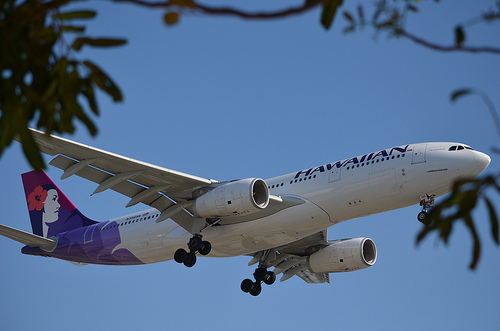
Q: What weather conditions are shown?
A: It is clear.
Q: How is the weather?
A: It is clear.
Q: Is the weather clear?
A: Yes, it is clear.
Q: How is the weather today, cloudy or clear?
A: It is clear.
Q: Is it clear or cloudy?
A: It is clear.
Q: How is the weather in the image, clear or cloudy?
A: It is clear.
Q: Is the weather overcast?
A: No, it is clear.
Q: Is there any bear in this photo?
A: No, there are no bears.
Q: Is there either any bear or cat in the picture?
A: No, there are no bears or cats.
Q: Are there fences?
A: No, there are no fences.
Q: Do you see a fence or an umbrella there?
A: No, there are no fences or umbrellas.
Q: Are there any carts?
A: No, there are no carts.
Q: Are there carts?
A: No, there are no carts.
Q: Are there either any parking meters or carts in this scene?
A: No, there are no carts or parking meters.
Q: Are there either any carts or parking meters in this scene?
A: No, there are no carts or parking meters.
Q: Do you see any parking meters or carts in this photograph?
A: No, there are no carts or parking meters.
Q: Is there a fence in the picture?
A: No, there are no fences.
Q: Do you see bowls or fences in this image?
A: No, there are no fences or bowls.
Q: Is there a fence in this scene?
A: No, there are no fences.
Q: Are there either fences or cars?
A: No, there are no fences or cars.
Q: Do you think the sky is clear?
A: Yes, the sky is clear.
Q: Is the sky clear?
A: Yes, the sky is clear.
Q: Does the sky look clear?
A: Yes, the sky is clear.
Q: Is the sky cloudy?
A: No, the sky is clear.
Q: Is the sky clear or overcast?
A: The sky is clear.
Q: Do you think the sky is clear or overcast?
A: The sky is clear.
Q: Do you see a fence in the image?
A: No, there are no fences.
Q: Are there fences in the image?
A: No, there are no fences.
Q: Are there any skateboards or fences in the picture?
A: No, there are no fences or skateboards.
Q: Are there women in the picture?
A: Yes, there is a woman.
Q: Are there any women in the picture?
A: Yes, there is a woman.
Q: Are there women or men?
A: Yes, there is a woman.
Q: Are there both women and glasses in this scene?
A: No, there is a woman but no glasses.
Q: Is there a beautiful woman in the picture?
A: Yes, there is a beautiful woman.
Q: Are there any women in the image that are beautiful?
A: Yes, there is a woman that is beautiful.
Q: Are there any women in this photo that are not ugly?
A: Yes, there is an beautiful woman.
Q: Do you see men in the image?
A: No, there are no men.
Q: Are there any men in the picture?
A: No, there are no men.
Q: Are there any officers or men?
A: No, there are no men or officers.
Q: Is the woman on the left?
A: Yes, the woman is on the left of the image.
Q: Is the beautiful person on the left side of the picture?
A: Yes, the woman is on the left of the image.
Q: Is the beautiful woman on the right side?
A: No, the woman is on the left of the image.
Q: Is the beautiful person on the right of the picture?
A: No, the woman is on the left of the image.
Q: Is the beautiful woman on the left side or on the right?
A: The woman is on the left of the image.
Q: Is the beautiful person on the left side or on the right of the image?
A: The woman is on the left of the image.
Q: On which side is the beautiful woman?
A: The woman is on the left of the image.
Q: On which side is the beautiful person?
A: The woman is on the left of the image.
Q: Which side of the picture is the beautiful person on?
A: The woman is on the left of the image.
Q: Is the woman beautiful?
A: Yes, the woman is beautiful.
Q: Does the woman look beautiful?
A: Yes, the woman is beautiful.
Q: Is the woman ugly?
A: No, the woman is beautiful.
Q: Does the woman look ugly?
A: No, the woman is beautiful.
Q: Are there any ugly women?
A: No, there is a woman but she is beautiful.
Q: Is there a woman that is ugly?
A: No, there is a woman but she is beautiful.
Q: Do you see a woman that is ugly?
A: No, there is a woman but she is beautiful.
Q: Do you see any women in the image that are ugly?
A: No, there is a woman but she is beautiful.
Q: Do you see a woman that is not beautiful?
A: No, there is a woman but she is beautiful.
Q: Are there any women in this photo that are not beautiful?
A: No, there is a woman but she is beautiful.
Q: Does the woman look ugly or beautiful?
A: The woman is beautiful.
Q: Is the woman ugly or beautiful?
A: The woman is beautiful.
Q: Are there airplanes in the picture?
A: Yes, there is an airplane.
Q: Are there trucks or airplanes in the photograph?
A: Yes, there is an airplane.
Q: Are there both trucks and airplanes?
A: No, there is an airplane but no trucks.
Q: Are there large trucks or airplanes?
A: Yes, there is a large airplane.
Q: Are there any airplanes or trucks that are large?
A: Yes, the airplane is large.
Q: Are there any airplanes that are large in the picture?
A: Yes, there is a large airplane.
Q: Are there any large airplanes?
A: Yes, there is a large airplane.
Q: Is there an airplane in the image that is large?
A: Yes, there is an airplane that is large.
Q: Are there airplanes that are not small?
A: Yes, there is a large airplane.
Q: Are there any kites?
A: No, there are no kites.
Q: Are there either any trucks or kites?
A: No, there are no kites or trucks.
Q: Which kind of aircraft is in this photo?
A: The aircraft is an airplane.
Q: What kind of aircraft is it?
A: The aircraft is an airplane.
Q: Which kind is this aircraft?
A: This is an airplane.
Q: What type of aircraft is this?
A: This is an airplane.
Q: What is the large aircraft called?
A: The aircraft is an airplane.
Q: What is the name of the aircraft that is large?
A: The aircraft is an airplane.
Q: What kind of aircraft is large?
A: The aircraft is an airplane.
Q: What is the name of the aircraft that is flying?
A: The aircraft is an airplane.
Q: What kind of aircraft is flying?
A: The aircraft is an airplane.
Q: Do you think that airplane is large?
A: Yes, the airplane is large.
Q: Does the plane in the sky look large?
A: Yes, the airplane is large.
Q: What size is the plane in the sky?
A: The plane is large.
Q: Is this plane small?
A: No, the plane is large.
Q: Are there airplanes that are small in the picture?
A: No, there is an airplane but it is large.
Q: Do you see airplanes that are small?
A: No, there is an airplane but it is large.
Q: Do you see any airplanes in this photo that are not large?
A: No, there is an airplane but it is large.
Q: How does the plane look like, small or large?
A: The plane is large.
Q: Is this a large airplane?
A: Yes, this is a large airplane.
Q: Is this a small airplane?
A: No, this is a large airplane.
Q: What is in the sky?
A: The plane is in the sky.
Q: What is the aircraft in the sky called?
A: The aircraft is an airplane.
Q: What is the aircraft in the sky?
A: The aircraft is an airplane.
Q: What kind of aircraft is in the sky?
A: The aircraft is an airplane.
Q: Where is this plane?
A: The plane is in the sky.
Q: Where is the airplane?
A: The plane is in the sky.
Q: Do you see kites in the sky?
A: No, there is an airplane in the sky.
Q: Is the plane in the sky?
A: Yes, the plane is in the sky.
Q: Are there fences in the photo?
A: No, there are no fences.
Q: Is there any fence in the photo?
A: No, there are no fences.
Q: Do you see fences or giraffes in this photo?
A: No, there are no fences or giraffes.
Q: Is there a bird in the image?
A: No, there are no birds.